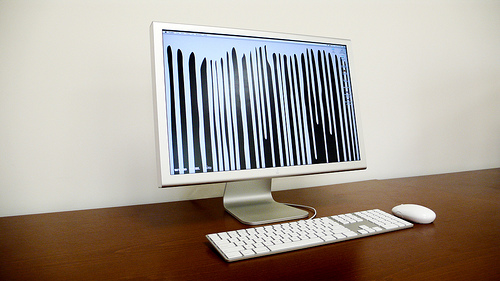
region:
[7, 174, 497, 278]
long wooden smooth desk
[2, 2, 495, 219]
cream painted wall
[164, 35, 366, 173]
black and white image on the screen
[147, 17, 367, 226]
white and silver computer monitor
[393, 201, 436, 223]
smooth white wireless mouse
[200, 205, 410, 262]
silver and white flat computer keyboard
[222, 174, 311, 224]
silver smooth computer stand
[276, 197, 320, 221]
white computer cord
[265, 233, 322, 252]
white computer space bar key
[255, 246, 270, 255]
white computer key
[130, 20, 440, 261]
one computer is seen.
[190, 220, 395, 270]
Keyboard is white color.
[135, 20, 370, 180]
Monitor screen is on.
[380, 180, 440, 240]
mouse is white color.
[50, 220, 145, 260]
table is brown color.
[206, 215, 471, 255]
keyboard and mouse is in table.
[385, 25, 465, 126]
Wall is white color.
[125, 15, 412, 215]
Monitor is white color.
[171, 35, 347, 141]
Blue and black lines in the screen.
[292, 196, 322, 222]
Wire is white color.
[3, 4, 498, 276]
Interior shot.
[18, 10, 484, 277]
Still life, showing office space and computer.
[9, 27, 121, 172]
White wall without decoration.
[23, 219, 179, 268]
Long, flat, wood surface, probably a desk.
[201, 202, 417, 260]
Slim keyboard with white keys.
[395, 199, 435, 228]
White mouse, beside keyboard, without mouse pad.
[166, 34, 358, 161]
Turned on screen.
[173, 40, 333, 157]
Site, showing scene reminiscent of wall with paint drips.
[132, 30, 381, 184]
Monitor with white border.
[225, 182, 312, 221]
Silver, metal base of monitor.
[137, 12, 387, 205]
a white computer monitor with white and black stripes on the screen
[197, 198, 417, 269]
a white and metal computer keyboard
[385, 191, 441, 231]
a white computer mouse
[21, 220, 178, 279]
a brown wooden empty desktop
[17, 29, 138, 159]
an empty white wall space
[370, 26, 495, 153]
an empty white wall space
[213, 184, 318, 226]
a metallic grey computer monitor stand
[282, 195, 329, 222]
a white cord connecting a keyboard to a monitor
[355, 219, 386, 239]
four white computer keys in an upside down T shape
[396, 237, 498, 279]
a brown wooden desk top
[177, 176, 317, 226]
sleek silver support holding screen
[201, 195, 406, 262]
thin and minimal keyboard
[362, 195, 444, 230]
cordless white mouse next to keyboard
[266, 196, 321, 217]
curved white wire connecting keyboard to monitor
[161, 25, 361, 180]
black lines against a light blue background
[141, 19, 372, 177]
light blue lines against a black background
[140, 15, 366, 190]
silver frame around screen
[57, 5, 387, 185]
white wall behind screen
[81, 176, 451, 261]
rich brown color of wood table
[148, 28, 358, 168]
some lines thinner and longer